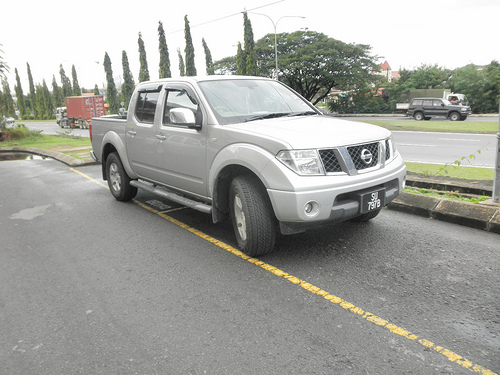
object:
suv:
[405, 96, 472, 123]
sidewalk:
[322, 114, 499, 122]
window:
[133, 90, 162, 125]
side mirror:
[166, 105, 197, 126]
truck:
[88, 73, 406, 257]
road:
[0, 148, 499, 374]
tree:
[120, 49, 135, 110]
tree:
[101, 50, 122, 115]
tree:
[182, 14, 197, 78]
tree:
[240, 11, 255, 75]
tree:
[156, 20, 171, 79]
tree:
[136, 30, 150, 83]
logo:
[356, 147, 373, 165]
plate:
[363, 190, 381, 212]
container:
[64, 94, 109, 119]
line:
[177, 220, 440, 350]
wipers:
[242, 109, 322, 121]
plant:
[30, 77, 58, 120]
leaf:
[292, 46, 312, 53]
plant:
[208, 31, 391, 111]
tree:
[199, 37, 216, 77]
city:
[0, 0, 498, 374]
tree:
[175, 12, 197, 77]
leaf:
[294, 58, 312, 67]